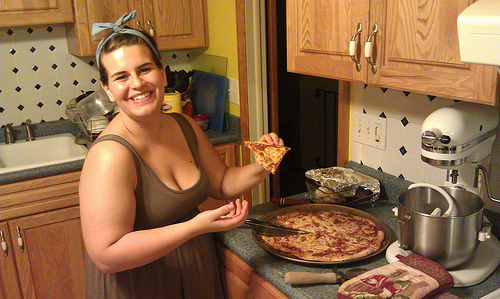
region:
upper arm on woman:
[89, 155, 126, 210]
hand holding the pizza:
[240, 130, 287, 172]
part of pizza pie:
[287, 209, 371, 262]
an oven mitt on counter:
[359, 252, 430, 295]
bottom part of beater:
[395, 177, 475, 249]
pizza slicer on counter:
[279, 256, 361, 278]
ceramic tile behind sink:
[13, 44, 63, 92]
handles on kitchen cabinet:
[351, 26, 376, 71]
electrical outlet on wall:
[352, 110, 387, 147]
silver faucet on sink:
[19, 117, 41, 141]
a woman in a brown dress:
[66, 14, 248, 281]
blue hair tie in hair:
[75, 5, 169, 65]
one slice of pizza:
[242, 123, 295, 201]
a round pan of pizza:
[248, 201, 396, 276]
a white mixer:
[416, 98, 498, 266]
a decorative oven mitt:
[332, 249, 466, 296]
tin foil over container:
[305, 163, 393, 202]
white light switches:
[345, 103, 402, 164]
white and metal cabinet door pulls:
[0, 208, 32, 275]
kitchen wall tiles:
[6, 41, 65, 113]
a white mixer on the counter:
[383, 97, 491, 283]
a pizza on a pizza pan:
[264, 197, 385, 262]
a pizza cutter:
[272, 263, 394, 297]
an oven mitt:
[333, 241, 473, 298]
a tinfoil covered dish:
[298, 157, 380, 203]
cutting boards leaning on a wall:
[186, 48, 228, 122]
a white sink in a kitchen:
[0, 102, 87, 169]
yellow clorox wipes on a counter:
[158, 89, 188, 125]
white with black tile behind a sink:
[3, 33, 94, 113]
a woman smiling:
[72, 18, 287, 297]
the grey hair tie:
[88, 11, 164, 81]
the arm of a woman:
[79, 138, 189, 268]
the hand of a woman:
[194, 197, 248, 232]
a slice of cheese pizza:
[246, 136, 288, 166]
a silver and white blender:
[395, 106, 499, 281]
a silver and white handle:
[13, 221, 25, 251]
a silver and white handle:
[347, 19, 364, 67]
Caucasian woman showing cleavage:
[68, 14, 228, 274]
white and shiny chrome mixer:
[398, 101, 499, 286]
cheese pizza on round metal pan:
[242, 198, 397, 268]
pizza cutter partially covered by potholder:
[278, 253, 457, 296]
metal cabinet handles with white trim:
[345, 21, 382, 78]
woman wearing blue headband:
[89, 6, 174, 140]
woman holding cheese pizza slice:
[64, 8, 290, 270]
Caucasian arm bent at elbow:
[68, 132, 255, 274]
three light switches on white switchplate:
[348, 106, 390, 151]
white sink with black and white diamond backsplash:
[2, 31, 81, 183]